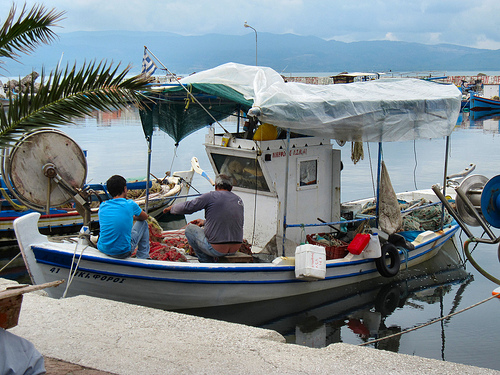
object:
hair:
[103, 174, 125, 196]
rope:
[62, 244, 90, 297]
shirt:
[96, 198, 143, 256]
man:
[96, 174, 150, 260]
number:
[49, 266, 56, 272]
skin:
[210, 241, 243, 253]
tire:
[376, 243, 401, 278]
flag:
[141, 46, 158, 78]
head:
[106, 174, 128, 198]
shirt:
[169, 190, 245, 243]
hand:
[187, 218, 205, 227]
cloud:
[435, 14, 490, 46]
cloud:
[421, 0, 488, 12]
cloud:
[291, 2, 388, 37]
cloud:
[150, 1, 260, 33]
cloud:
[30, 0, 127, 31]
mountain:
[0, 26, 500, 76]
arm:
[131, 200, 149, 221]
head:
[214, 174, 234, 191]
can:
[292, 242, 328, 282]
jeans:
[184, 223, 237, 263]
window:
[298, 157, 321, 189]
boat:
[12, 61, 463, 311]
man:
[163, 173, 245, 263]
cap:
[213, 173, 234, 186]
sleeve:
[132, 201, 142, 215]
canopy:
[121, 57, 461, 156]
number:
[55, 267, 62, 273]